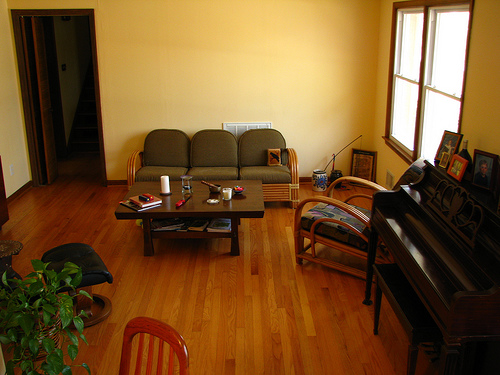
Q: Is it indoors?
A: Yes, it is indoors.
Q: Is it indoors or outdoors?
A: It is indoors.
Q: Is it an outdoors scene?
A: No, it is indoors.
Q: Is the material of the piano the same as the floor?
A: Yes, both the piano and the floor are made of wood.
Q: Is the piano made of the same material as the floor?
A: Yes, both the piano and the floor are made of wood.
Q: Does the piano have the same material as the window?
A: Yes, both the piano and the window are made of wood.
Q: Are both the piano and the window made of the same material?
A: Yes, both the piano and the window are made of wood.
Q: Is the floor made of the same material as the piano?
A: Yes, both the floor and the piano are made of wood.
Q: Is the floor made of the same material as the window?
A: Yes, both the floor and the window are made of wood.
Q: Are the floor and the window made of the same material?
A: Yes, both the floor and the window are made of wood.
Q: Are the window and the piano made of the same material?
A: Yes, both the window and the piano are made of wood.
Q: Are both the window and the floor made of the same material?
A: Yes, both the window and the floor are made of wood.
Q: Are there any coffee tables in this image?
A: Yes, there is a coffee table.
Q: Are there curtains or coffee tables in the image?
A: Yes, there is a coffee table.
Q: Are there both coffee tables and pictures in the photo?
A: Yes, there are both a coffee table and a picture.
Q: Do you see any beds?
A: No, there are no beds.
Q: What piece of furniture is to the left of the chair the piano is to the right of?
A: The piece of furniture is a coffee table.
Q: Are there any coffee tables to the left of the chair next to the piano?
A: Yes, there is a coffee table to the left of the chair.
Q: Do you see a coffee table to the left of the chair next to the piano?
A: Yes, there is a coffee table to the left of the chair.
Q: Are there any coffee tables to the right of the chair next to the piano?
A: No, the coffee table is to the left of the chair.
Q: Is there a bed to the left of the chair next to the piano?
A: No, there is a coffee table to the left of the chair.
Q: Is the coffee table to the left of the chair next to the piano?
A: Yes, the coffee table is to the left of the chair.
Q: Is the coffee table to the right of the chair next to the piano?
A: No, the coffee table is to the left of the chair.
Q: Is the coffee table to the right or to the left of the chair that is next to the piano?
A: The coffee table is to the left of the chair.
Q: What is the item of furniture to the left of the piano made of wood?
A: The piece of furniture is a coffee table.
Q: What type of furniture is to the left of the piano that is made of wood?
A: The piece of furniture is a coffee table.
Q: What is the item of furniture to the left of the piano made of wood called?
A: The piece of furniture is a coffee table.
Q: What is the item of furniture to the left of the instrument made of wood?
A: The piece of furniture is a coffee table.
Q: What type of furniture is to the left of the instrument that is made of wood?
A: The piece of furniture is a coffee table.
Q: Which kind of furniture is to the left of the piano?
A: The piece of furniture is a coffee table.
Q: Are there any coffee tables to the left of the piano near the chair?
A: Yes, there is a coffee table to the left of the piano.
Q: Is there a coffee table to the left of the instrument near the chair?
A: Yes, there is a coffee table to the left of the piano.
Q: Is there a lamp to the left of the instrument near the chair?
A: No, there is a coffee table to the left of the piano.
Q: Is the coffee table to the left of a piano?
A: Yes, the coffee table is to the left of a piano.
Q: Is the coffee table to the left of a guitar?
A: No, the coffee table is to the left of a piano.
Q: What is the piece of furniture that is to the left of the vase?
A: The piece of furniture is a coffee table.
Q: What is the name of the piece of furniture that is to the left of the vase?
A: The piece of furniture is a coffee table.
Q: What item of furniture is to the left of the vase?
A: The piece of furniture is a coffee table.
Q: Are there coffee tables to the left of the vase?
A: Yes, there is a coffee table to the left of the vase.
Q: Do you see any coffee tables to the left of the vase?
A: Yes, there is a coffee table to the left of the vase.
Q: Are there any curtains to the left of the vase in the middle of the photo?
A: No, there is a coffee table to the left of the vase.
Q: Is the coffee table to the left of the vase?
A: Yes, the coffee table is to the left of the vase.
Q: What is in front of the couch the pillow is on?
A: The coffee table is in front of the couch.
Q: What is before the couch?
A: The coffee table is in front of the couch.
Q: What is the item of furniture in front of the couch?
A: The piece of furniture is a coffee table.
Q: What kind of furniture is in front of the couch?
A: The piece of furniture is a coffee table.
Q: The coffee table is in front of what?
A: The coffee table is in front of the couch.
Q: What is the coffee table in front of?
A: The coffee table is in front of the couch.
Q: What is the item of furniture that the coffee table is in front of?
A: The piece of furniture is a couch.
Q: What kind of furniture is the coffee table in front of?
A: The coffee table is in front of the couch.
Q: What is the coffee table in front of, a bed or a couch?
A: The coffee table is in front of a couch.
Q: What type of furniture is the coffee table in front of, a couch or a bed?
A: The coffee table is in front of a couch.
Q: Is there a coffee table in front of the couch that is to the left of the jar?
A: Yes, there is a coffee table in front of the couch.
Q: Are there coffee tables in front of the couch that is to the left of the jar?
A: Yes, there is a coffee table in front of the couch.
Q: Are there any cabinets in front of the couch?
A: No, there is a coffee table in front of the couch.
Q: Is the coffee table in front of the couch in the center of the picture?
A: Yes, the coffee table is in front of the couch.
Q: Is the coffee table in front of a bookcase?
A: No, the coffee table is in front of the couch.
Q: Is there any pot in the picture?
A: No, there are no pots.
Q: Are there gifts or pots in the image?
A: No, there are no pots or gifts.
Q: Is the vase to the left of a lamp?
A: No, the vase is to the left of a picture.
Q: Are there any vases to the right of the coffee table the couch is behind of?
A: Yes, there is a vase to the right of the coffee table.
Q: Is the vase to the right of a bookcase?
A: No, the vase is to the right of a coffee table.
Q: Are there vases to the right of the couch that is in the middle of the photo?
A: Yes, there is a vase to the right of the couch.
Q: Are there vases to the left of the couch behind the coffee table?
A: No, the vase is to the right of the couch.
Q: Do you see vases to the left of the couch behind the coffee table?
A: No, the vase is to the right of the couch.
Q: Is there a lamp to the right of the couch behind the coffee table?
A: No, there is a vase to the right of the couch.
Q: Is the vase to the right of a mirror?
A: No, the vase is to the right of a couch.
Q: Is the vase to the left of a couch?
A: No, the vase is to the right of a couch.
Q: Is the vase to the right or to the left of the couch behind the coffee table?
A: The vase is to the right of the couch.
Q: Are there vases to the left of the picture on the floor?
A: Yes, there is a vase to the left of the picture.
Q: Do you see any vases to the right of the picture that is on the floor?
A: No, the vase is to the left of the picture.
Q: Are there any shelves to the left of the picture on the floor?
A: No, there is a vase to the left of the picture.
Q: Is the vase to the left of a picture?
A: Yes, the vase is to the left of a picture.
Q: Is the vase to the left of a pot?
A: No, the vase is to the left of a picture.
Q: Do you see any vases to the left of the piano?
A: Yes, there is a vase to the left of the piano.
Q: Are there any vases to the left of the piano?
A: Yes, there is a vase to the left of the piano.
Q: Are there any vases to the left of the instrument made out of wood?
A: Yes, there is a vase to the left of the piano.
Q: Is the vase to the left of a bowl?
A: No, the vase is to the left of a piano.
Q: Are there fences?
A: No, there are no fences.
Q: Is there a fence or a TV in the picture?
A: No, there are no fences or televisions.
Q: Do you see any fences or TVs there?
A: No, there are no fences or tvs.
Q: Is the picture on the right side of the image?
A: Yes, the picture is on the right of the image.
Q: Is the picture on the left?
A: No, the picture is on the right of the image.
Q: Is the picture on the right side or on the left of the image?
A: The picture is on the right of the image.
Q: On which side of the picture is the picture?
A: The picture is on the right of the image.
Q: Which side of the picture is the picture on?
A: The picture is on the right of the image.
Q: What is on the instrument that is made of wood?
A: The picture is on the piano.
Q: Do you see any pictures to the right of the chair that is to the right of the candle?
A: Yes, there is a picture to the right of the chair.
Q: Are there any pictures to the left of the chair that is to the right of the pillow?
A: No, the picture is to the right of the chair.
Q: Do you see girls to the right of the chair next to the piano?
A: No, there is a picture to the right of the chair.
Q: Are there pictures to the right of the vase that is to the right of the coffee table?
A: Yes, there is a picture to the right of the vase.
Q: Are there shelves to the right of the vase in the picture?
A: No, there is a picture to the right of the vase.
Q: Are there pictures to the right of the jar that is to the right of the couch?
A: Yes, there is a picture to the right of the jar.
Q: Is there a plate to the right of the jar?
A: No, there is a picture to the right of the jar.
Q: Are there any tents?
A: No, there are no tents.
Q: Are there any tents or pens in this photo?
A: No, there are no tents or pens.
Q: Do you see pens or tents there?
A: No, there are no tents or pens.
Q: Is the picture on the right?
A: Yes, the picture is on the right of the image.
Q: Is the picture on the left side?
A: No, the picture is on the right of the image.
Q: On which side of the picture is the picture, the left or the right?
A: The picture is on the right of the image.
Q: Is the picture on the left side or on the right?
A: The picture is on the right of the image.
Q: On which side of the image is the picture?
A: The picture is on the right of the image.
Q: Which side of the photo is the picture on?
A: The picture is on the right of the image.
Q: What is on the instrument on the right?
A: The picture is on the piano.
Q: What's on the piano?
A: The picture is on the piano.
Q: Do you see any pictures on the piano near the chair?
A: Yes, there is a picture on the piano.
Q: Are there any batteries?
A: No, there are no batteries.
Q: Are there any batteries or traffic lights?
A: No, there are no batteries or traffic lights.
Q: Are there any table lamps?
A: No, there are no table lamps.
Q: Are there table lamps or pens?
A: No, there are no table lamps or pens.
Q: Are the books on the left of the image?
A: Yes, the books are on the left of the image.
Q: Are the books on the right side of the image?
A: No, the books are on the left of the image.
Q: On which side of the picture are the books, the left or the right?
A: The books are on the left of the image.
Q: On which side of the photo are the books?
A: The books are on the left of the image.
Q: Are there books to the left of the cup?
A: Yes, there are books to the left of the cup.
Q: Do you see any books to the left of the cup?
A: Yes, there are books to the left of the cup.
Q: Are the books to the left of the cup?
A: Yes, the books are to the left of the cup.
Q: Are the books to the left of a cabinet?
A: No, the books are to the left of the cup.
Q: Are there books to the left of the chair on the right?
A: Yes, there are books to the left of the chair.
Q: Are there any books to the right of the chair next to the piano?
A: No, the books are to the left of the chair.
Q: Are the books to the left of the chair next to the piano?
A: Yes, the books are to the left of the chair.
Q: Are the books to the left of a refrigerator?
A: No, the books are to the left of the chair.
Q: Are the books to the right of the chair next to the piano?
A: No, the books are to the left of the chair.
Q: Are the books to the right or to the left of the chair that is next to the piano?
A: The books are to the left of the chair.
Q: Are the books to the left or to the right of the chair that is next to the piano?
A: The books are to the left of the chair.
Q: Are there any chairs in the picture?
A: Yes, there is a chair.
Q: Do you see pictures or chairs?
A: Yes, there is a chair.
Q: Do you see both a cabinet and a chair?
A: No, there is a chair but no cabinets.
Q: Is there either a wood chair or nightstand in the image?
A: Yes, there is a wood chair.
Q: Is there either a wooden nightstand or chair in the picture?
A: Yes, there is a wood chair.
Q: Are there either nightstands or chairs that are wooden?
A: Yes, the chair is wooden.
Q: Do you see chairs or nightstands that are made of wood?
A: Yes, the chair is made of wood.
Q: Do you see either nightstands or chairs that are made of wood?
A: Yes, the chair is made of wood.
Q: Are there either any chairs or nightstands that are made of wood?
A: Yes, the chair is made of wood.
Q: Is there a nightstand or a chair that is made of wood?
A: Yes, the chair is made of wood.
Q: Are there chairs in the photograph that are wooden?
A: Yes, there is a wood chair.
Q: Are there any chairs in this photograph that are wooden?
A: Yes, there is a chair that is wooden.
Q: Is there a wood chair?
A: Yes, there is a chair that is made of wood.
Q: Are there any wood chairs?
A: Yes, there is a chair that is made of wood.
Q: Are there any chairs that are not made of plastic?
A: Yes, there is a chair that is made of wood.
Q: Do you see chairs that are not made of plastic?
A: Yes, there is a chair that is made of wood.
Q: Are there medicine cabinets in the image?
A: No, there are no medicine cabinets.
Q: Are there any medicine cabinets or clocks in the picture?
A: No, there are no medicine cabinets or clocks.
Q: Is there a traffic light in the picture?
A: No, there are no traffic lights.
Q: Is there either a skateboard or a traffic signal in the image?
A: No, there are no traffic lights or skateboards.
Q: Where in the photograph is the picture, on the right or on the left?
A: The picture is on the right of the image.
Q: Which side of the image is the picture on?
A: The picture is on the right of the image.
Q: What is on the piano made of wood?
A: The picture is on the piano.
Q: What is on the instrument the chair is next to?
A: The picture is on the piano.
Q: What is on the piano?
A: The picture is on the piano.